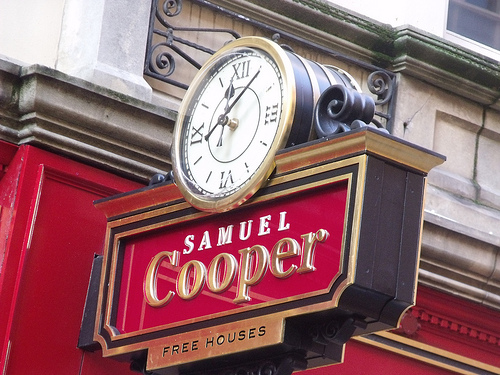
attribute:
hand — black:
[203, 71, 254, 147]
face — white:
[188, 81, 281, 166]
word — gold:
[121, 235, 363, 314]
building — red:
[9, 5, 120, 340]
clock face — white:
[181, 51, 282, 194]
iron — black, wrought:
[150, 1, 391, 128]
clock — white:
[172, 35, 363, 223]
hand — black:
[204, 64, 261, 141]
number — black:
[230, 62, 250, 82]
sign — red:
[115, 180, 345, 332]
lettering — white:
[181, 214, 290, 252]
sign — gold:
[153, 319, 287, 371]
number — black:
[228, 58, 253, 82]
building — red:
[2, 64, 492, 373]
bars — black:
[147, 2, 398, 141]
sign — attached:
[89, 155, 361, 373]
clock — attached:
[166, 26, 296, 224]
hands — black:
[195, 60, 269, 150]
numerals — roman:
[184, 48, 282, 197]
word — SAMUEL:
[173, 205, 296, 265]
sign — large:
[78, 121, 438, 362]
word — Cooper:
[132, 229, 331, 310]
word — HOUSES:
[201, 314, 276, 354]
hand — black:
[210, 61, 243, 151]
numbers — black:
[185, 51, 288, 199]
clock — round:
[162, 28, 341, 219]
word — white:
[174, 201, 299, 259]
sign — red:
[104, 147, 372, 343]